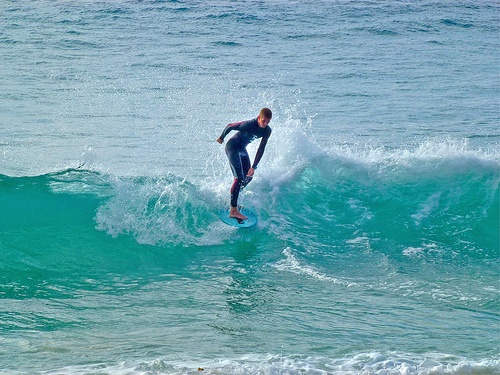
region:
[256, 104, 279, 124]
head of a person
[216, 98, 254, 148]
arm of a person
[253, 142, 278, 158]
arm of a person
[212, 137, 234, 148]
hand of a person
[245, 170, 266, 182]
hand of a person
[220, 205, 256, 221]
feet of a person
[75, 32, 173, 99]
body of a water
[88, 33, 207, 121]
clear body of water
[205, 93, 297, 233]
person on a board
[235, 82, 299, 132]
the head of a man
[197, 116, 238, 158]
the arm of a man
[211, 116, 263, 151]
the arm of a man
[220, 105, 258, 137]
the shoulder of a man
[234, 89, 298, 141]
the face of a man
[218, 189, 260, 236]
the feet of a man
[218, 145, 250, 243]
the leg of a man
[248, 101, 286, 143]
the eye of a man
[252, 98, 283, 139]
the nose of a man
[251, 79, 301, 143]
the chin of a man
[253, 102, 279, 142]
head of a person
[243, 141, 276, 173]
arm of a person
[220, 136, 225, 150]
hand of a person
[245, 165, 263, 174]
hand of a person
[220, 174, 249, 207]
leg of a person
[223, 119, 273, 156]
body of a person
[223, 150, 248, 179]
thigh of a person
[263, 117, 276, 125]
nose of a person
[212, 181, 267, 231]
Man on a board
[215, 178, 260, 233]
Man is on a board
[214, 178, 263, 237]
Man on a surfboard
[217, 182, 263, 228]
Man is on a surfboard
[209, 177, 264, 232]
Man on a blue board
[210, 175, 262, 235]
Man is on a blue board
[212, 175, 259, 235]
Man on a blue surfboard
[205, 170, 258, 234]
Man is on a blue surfboard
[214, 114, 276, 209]
Man wearing a wet suit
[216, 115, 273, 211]
Man is wearing a wet suit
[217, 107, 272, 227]
a man on a surfboard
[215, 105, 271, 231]
a man surfing on a wave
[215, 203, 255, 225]
edge of a blue surfboard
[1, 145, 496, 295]
a wave on the ocean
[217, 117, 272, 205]
man wearing a wet suit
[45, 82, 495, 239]
white foam on a wave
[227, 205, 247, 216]
man barefoot on a surfboard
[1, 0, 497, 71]
calm water behind a wave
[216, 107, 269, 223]
man keeping his balance on a surfboard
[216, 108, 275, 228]
a man standing on a surfboard